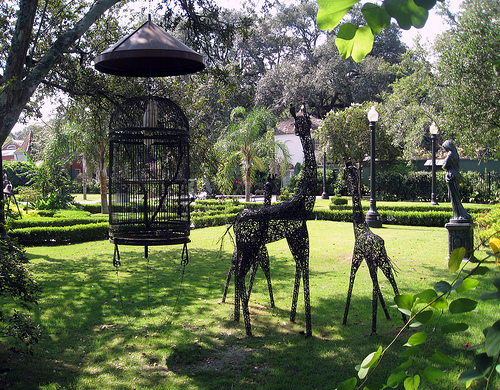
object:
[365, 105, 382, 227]
street lamp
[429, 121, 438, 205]
street lamp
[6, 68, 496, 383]
courtyard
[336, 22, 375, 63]
leaf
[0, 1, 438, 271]
tree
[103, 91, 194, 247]
black cage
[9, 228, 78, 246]
shrubbery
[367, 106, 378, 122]
lamp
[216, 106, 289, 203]
tree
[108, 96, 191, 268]
bell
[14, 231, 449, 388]
grass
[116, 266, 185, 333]
chains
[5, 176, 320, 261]
hedge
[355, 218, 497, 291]
ground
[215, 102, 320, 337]
iron giraffe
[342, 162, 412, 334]
iron giraffe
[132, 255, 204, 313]
shadows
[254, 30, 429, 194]
trees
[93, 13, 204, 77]
hood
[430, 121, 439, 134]
lamp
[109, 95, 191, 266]
birdcage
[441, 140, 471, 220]
statue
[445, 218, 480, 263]
base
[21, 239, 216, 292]
ground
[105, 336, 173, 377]
worn patch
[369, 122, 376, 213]
post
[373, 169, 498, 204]
hedge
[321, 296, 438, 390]
shade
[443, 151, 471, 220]
dress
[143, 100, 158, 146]
bird